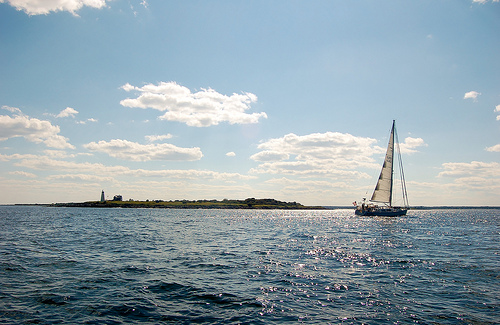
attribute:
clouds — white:
[128, 72, 273, 132]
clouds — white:
[55, 105, 97, 126]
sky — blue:
[23, 72, 133, 139]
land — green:
[79, 191, 318, 212]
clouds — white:
[121, 82, 268, 129]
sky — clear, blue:
[2, 0, 498, 208]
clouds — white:
[7, 0, 114, 15]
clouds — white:
[51, 102, 79, 119]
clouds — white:
[263, 130, 372, 159]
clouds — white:
[87, 134, 204, 163]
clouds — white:
[458, 85, 481, 102]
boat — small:
[356, 117, 408, 218]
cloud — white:
[120, 75, 268, 128]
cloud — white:
[9, 1, 105, 19]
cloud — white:
[54, 106, 81, 121]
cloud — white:
[250, 132, 379, 168]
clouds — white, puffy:
[122, 74, 273, 134]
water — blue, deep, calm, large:
[2, 203, 498, 322]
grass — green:
[168, 198, 219, 205]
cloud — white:
[118, 79, 266, 136]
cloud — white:
[251, 133, 425, 177]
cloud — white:
[86, 135, 205, 168]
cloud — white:
[1, 108, 73, 157]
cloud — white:
[1, 0, 116, 22]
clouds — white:
[118, 73, 265, 138]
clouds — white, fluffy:
[118, 77, 272, 129]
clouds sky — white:
[45, 38, 265, 130]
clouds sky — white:
[241, 130, 351, 185]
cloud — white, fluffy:
[79, 136, 206, 164]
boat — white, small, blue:
[348, 115, 413, 216]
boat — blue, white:
[351, 119, 411, 216]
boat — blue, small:
[339, 99, 426, 230]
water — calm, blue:
[93, 213, 271, 312]